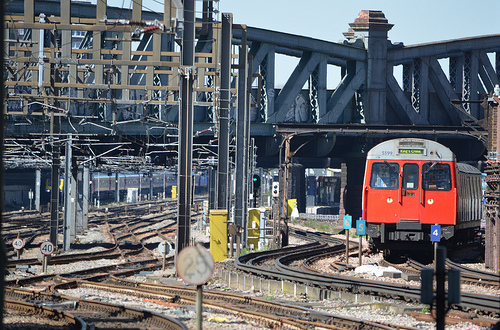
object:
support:
[178, 0, 195, 251]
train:
[362, 137, 484, 262]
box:
[209, 210, 228, 260]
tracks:
[233, 239, 499, 320]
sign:
[175, 246, 215, 286]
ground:
[2, 286, 499, 329]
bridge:
[0, 1, 499, 137]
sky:
[82, 1, 500, 38]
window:
[369, 162, 401, 190]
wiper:
[384, 160, 400, 176]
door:
[399, 162, 421, 223]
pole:
[193, 285, 204, 329]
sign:
[399, 150, 422, 154]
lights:
[387, 197, 393, 203]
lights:
[428, 199, 434, 205]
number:
[433, 229, 438, 236]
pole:
[433, 245, 444, 329]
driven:
[424, 165, 450, 189]